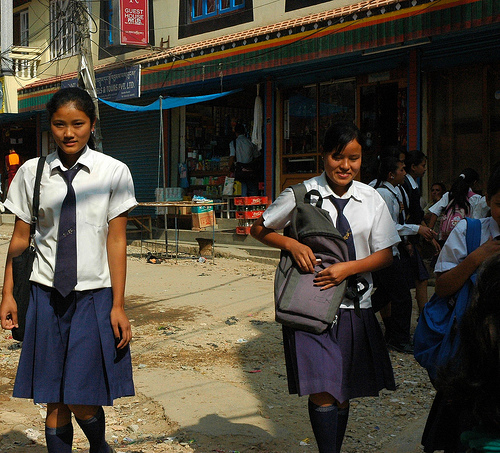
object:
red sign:
[120, 1, 148, 46]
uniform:
[2, 142, 140, 406]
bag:
[13, 155, 48, 340]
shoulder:
[21, 150, 51, 170]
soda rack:
[236, 210, 268, 220]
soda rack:
[233, 225, 263, 236]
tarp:
[97, 89, 235, 112]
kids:
[427, 167, 487, 268]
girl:
[247, 122, 402, 453]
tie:
[329, 195, 356, 299]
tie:
[53, 164, 81, 299]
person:
[228, 123, 257, 198]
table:
[136, 201, 228, 265]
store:
[179, 90, 265, 230]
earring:
[90, 129, 94, 135]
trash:
[403, 380, 418, 387]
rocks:
[396, 408, 407, 415]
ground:
[0, 223, 436, 451]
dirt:
[120, 288, 200, 330]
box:
[191, 209, 217, 229]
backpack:
[273, 180, 351, 335]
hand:
[311, 261, 347, 290]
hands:
[292, 243, 317, 274]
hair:
[47, 86, 97, 127]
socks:
[307, 399, 339, 451]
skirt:
[13, 284, 135, 405]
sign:
[60, 63, 142, 106]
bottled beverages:
[242, 205, 248, 211]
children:
[0, 86, 137, 452]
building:
[0, 0, 499, 266]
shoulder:
[285, 177, 314, 202]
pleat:
[90, 293, 113, 405]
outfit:
[262, 171, 402, 404]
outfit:
[2, 143, 139, 406]